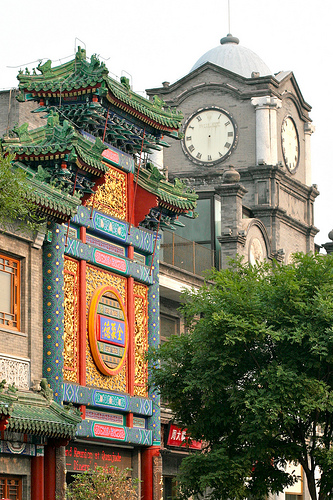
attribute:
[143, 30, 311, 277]
clock tower — stone, grey, tall, gray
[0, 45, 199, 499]
building — chinese pagoda, decorative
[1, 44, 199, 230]
roof — green colored, green, asian themed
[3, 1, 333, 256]
sky — cloudy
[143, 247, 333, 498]
tree — leafy, beautiful, green, huge, large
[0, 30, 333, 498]
buildings — asian, chinese style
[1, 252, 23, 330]
window — opaue glass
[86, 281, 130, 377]
sign — orange, circular, colorful, asian, chinese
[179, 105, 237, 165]
clock — old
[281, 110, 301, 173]
clock — old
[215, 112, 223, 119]
roman numeral — 1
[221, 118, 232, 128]
roman numeral — 2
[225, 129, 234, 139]
roman numeral — 3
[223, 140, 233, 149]
roman numeral — 4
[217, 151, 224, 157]
roman numeral — 5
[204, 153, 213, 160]
roman numeral — 6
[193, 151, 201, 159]
roman numeral — 7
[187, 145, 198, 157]
roman numeral — 8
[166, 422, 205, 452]
sign — chinese, red, asian, rectangular, white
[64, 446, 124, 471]
text — red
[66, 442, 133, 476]
sign — asian, black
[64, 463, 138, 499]
tree — small, green